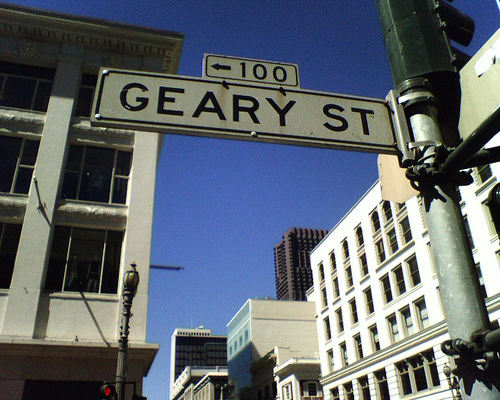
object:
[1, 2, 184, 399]
white building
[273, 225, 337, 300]
building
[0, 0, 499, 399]
sky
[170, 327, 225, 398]
building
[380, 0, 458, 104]
electric signal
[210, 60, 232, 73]
arrow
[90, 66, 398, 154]
sign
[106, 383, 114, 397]
light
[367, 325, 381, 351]
window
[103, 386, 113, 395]
light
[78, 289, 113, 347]
shadow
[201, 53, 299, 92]
sign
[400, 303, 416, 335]
window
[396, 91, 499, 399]
pole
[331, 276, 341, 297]
window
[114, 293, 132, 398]
pole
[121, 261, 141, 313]
street lamp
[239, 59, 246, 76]
numbers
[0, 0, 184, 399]
building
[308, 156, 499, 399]
building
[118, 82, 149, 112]
lettering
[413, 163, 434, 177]
bolts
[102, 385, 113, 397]
signal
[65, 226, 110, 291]
windows